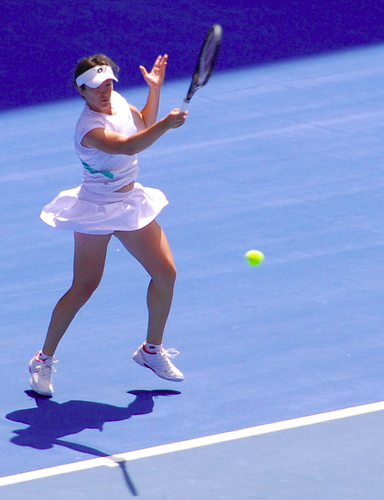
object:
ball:
[244, 249, 265, 267]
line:
[0, 400, 382, 488]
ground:
[0, 0, 383, 499]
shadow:
[4, 389, 182, 498]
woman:
[27, 51, 188, 396]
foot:
[28, 354, 56, 401]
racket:
[178, 22, 224, 115]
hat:
[73, 64, 119, 90]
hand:
[164, 107, 186, 131]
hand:
[136, 53, 168, 91]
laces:
[155, 344, 181, 370]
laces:
[34, 357, 57, 388]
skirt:
[38, 184, 169, 235]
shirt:
[72, 89, 139, 195]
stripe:
[78, 157, 113, 183]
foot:
[131, 342, 184, 383]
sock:
[36, 348, 56, 367]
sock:
[144, 341, 166, 353]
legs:
[40, 229, 114, 357]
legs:
[112, 219, 176, 348]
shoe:
[26, 353, 57, 399]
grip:
[177, 97, 191, 116]